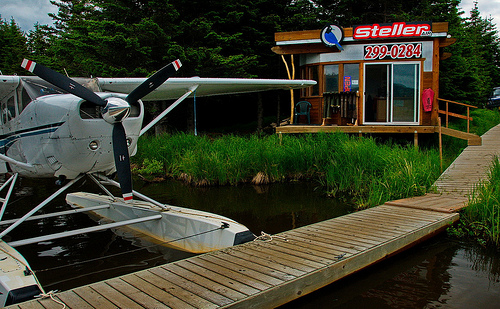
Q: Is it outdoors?
A: Yes, it is outdoors.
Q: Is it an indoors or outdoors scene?
A: It is outdoors.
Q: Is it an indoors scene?
A: No, it is outdoors.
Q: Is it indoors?
A: No, it is outdoors.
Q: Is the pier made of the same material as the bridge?
A: Yes, both the pier and the bridge are made of wood.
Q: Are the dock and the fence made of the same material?
A: Yes, both the dock and the fence are made of wood.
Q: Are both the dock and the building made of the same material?
A: Yes, both the dock and the building are made of wood.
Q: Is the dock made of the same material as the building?
A: Yes, both the dock and the building are made of wood.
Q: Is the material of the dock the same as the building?
A: Yes, both the dock and the building are made of wood.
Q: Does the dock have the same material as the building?
A: Yes, both the dock and the building are made of wood.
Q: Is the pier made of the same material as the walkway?
A: Yes, both the pier and the walkway are made of wood.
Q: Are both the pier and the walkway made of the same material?
A: Yes, both the pier and the walkway are made of wood.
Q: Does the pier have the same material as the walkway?
A: Yes, both the pier and the walkway are made of wood.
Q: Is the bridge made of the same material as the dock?
A: Yes, both the bridge and the dock are made of wood.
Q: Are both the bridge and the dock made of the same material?
A: Yes, both the bridge and the dock are made of wood.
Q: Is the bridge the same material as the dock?
A: Yes, both the bridge and the dock are made of wood.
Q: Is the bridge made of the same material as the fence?
A: Yes, both the bridge and the fence are made of wood.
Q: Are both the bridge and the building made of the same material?
A: Yes, both the bridge and the building are made of wood.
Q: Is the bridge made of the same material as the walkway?
A: Yes, both the bridge and the walkway are made of wood.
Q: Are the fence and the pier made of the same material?
A: Yes, both the fence and the pier are made of wood.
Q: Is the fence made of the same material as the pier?
A: Yes, both the fence and the pier are made of wood.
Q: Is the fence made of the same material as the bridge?
A: Yes, both the fence and the bridge are made of wood.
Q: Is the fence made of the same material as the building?
A: Yes, both the fence and the building are made of wood.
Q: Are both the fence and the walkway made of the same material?
A: Yes, both the fence and the walkway are made of wood.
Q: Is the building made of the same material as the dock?
A: Yes, both the building and the dock are made of wood.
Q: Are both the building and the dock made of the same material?
A: Yes, both the building and the dock are made of wood.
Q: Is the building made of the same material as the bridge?
A: Yes, both the building and the bridge are made of wood.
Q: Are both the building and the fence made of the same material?
A: Yes, both the building and the fence are made of wood.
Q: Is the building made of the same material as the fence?
A: Yes, both the building and the fence are made of wood.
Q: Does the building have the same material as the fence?
A: Yes, both the building and the fence are made of wood.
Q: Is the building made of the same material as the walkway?
A: Yes, both the building and the walkway are made of wood.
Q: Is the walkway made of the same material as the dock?
A: Yes, both the walkway and the dock are made of wood.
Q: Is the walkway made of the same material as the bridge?
A: Yes, both the walkway and the bridge are made of wood.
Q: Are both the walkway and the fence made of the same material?
A: Yes, both the walkway and the fence are made of wood.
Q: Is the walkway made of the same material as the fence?
A: Yes, both the walkway and the fence are made of wood.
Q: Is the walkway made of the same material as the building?
A: Yes, both the walkway and the building are made of wood.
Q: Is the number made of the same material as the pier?
A: No, the number is made of glass and the pier is made of wood.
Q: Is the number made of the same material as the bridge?
A: No, the number is made of glass and the bridge is made of wood.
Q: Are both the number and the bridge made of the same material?
A: No, the number is made of glass and the bridge is made of wood.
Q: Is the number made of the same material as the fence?
A: No, the number is made of glass and the fence is made of wood.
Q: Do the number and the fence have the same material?
A: No, the number is made of glass and the fence is made of wood.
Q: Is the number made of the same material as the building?
A: No, the number is made of glass and the building is made of wood.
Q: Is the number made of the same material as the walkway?
A: No, the number is made of glass and the walkway is made of wood.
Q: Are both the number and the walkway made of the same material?
A: No, the number is made of glass and the walkway is made of wood.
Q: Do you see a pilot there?
A: No, there are no pilots.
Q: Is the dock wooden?
A: Yes, the dock is wooden.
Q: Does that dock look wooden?
A: Yes, the dock is wooden.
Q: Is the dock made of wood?
A: Yes, the dock is made of wood.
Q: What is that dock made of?
A: The dock is made of wood.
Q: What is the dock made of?
A: The dock is made of wood.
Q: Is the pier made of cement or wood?
A: The pier is made of wood.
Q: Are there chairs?
A: Yes, there is a chair.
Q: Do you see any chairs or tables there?
A: Yes, there is a chair.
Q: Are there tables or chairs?
A: Yes, there is a chair.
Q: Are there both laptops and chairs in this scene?
A: No, there is a chair but no laptops.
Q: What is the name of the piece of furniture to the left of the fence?
A: The piece of furniture is a chair.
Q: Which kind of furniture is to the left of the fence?
A: The piece of furniture is a chair.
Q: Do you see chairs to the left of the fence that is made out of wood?
A: Yes, there is a chair to the left of the fence.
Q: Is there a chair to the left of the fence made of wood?
A: Yes, there is a chair to the left of the fence.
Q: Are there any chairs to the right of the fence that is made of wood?
A: No, the chair is to the left of the fence.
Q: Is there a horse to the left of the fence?
A: No, there is a chair to the left of the fence.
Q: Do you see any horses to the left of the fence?
A: No, there is a chair to the left of the fence.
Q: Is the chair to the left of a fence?
A: Yes, the chair is to the left of a fence.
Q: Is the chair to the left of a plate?
A: No, the chair is to the left of a fence.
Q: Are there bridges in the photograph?
A: Yes, there is a bridge.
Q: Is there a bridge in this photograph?
A: Yes, there is a bridge.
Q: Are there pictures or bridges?
A: Yes, there is a bridge.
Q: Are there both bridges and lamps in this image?
A: No, there is a bridge but no lamps.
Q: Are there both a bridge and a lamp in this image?
A: No, there is a bridge but no lamps.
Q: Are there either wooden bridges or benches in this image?
A: Yes, there is a wood bridge.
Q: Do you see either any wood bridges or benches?
A: Yes, there is a wood bridge.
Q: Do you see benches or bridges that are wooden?
A: Yes, the bridge is wooden.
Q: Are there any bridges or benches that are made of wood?
A: Yes, the bridge is made of wood.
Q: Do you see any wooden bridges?
A: Yes, there is a wood bridge.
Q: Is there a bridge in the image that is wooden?
A: Yes, there is a bridge that is wooden.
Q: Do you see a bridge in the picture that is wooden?
A: Yes, there is a bridge that is wooden.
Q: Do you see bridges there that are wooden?
A: Yes, there is a bridge that is wooden.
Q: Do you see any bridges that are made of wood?
A: Yes, there is a bridge that is made of wood.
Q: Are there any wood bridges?
A: Yes, there is a bridge that is made of wood.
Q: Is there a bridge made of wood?
A: Yes, there is a bridge that is made of wood.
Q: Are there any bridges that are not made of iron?
A: Yes, there is a bridge that is made of wood.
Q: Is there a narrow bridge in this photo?
A: Yes, there is a narrow bridge.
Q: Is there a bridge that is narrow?
A: Yes, there is a bridge that is narrow.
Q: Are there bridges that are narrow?
A: Yes, there is a bridge that is narrow.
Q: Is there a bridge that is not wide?
A: Yes, there is a narrow bridge.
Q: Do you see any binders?
A: No, there are no binders.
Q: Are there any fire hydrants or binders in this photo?
A: No, there are no binders or fire hydrants.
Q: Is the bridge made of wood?
A: Yes, the bridge is made of wood.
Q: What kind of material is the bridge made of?
A: The bridge is made of wood.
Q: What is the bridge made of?
A: The bridge is made of wood.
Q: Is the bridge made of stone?
A: No, the bridge is made of wood.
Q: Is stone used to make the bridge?
A: No, the bridge is made of wood.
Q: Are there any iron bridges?
A: No, there is a bridge but it is made of wood.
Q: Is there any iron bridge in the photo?
A: No, there is a bridge but it is made of wood.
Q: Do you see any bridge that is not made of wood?
A: No, there is a bridge but it is made of wood.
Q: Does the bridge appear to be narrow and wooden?
A: Yes, the bridge is narrow and wooden.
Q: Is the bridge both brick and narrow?
A: No, the bridge is narrow but wooden.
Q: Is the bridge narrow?
A: Yes, the bridge is narrow.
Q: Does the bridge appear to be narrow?
A: Yes, the bridge is narrow.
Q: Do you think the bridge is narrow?
A: Yes, the bridge is narrow.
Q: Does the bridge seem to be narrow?
A: Yes, the bridge is narrow.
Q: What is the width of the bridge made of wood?
A: The bridge is narrow.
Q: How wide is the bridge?
A: The bridge is narrow.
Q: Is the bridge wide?
A: No, the bridge is narrow.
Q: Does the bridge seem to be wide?
A: No, the bridge is narrow.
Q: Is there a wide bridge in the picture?
A: No, there is a bridge but it is narrow.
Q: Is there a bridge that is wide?
A: No, there is a bridge but it is narrow.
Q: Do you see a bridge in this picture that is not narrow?
A: No, there is a bridge but it is narrow.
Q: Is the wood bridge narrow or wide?
A: The bridge is narrow.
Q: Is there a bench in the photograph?
A: No, there are no benches.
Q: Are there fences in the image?
A: Yes, there is a fence.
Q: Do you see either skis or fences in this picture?
A: Yes, there is a fence.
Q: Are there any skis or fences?
A: Yes, there is a fence.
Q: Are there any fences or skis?
A: Yes, there is a fence.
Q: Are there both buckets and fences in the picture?
A: No, there is a fence but no buckets.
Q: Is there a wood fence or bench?
A: Yes, there is a wood fence.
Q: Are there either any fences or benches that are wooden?
A: Yes, the fence is wooden.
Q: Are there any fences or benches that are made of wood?
A: Yes, the fence is made of wood.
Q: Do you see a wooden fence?
A: Yes, there is a wood fence.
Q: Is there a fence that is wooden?
A: Yes, there is a fence that is wooden.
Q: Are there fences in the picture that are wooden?
A: Yes, there is a fence that is wooden.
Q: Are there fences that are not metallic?
A: Yes, there is a wooden fence.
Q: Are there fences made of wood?
A: Yes, there is a fence that is made of wood.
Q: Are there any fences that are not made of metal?
A: Yes, there is a fence that is made of wood.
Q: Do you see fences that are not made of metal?
A: Yes, there is a fence that is made of wood.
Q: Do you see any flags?
A: No, there are no flags.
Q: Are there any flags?
A: No, there are no flags.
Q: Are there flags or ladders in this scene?
A: No, there are no flags or ladders.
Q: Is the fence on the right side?
A: Yes, the fence is on the right of the image.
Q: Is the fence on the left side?
A: No, the fence is on the right of the image.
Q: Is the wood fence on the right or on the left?
A: The fence is on the right of the image.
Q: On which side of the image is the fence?
A: The fence is on the right of the image.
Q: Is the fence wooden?
A: Yes, the fence is wooden.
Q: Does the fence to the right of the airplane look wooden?
A: Yes, the fence is wooden.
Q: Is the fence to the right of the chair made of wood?
A: Yes, the fence is made of wood.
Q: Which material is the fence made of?
A: The fence is made of wood.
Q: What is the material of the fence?
A: The fence is made of wood.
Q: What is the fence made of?
A: The fence is made of wood.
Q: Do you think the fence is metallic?
A: No, the fence is wooden.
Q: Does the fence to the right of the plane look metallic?
A: No, the fence is wooden.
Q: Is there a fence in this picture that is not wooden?
A: No, there is a fence but it is wooden.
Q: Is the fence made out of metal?
A: No, the fence is made of wood.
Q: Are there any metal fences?
A: No, there is a fence but it is made of wood.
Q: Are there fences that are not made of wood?
A: No, there is a fence but it is made of wood.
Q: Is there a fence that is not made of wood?
A: No, there is a fence but it is made of wood.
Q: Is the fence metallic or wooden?
A: The fence is wooden.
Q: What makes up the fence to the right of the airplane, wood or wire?
A: The fence is made of wood.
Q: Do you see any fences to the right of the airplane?
A: Yes, there is a fence to the right of the airplane.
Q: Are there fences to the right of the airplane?
A: Yes, there is a fence to the right of the airplane.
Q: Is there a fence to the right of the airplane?
A: Yes, there is a fence to the right of the airplane.